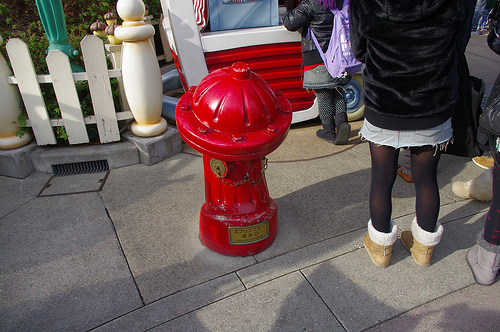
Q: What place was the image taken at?
A: It was taken at the sidewalk.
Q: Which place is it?
A: It is a sidewalk.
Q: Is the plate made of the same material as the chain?
A: Yes, both the plate and the chain are made of metal.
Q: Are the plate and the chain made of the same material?
A: Yes, both the plate and the chain are made of metal.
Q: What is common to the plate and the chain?
A: The material, both the plate and the chain are metallic.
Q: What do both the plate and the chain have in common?
A: The material, both the plate and the chain are metallic.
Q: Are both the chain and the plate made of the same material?
A: Yes, both the chain and the plate are made of metal.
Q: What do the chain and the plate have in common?
A: The material, both the chain and the plate are metallic.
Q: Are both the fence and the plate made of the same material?
A: No, the fence is made of wood and the plate is made of metal.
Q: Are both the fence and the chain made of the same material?
A: No, the fence is made of wood and the chain is made of metal.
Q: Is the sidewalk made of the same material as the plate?
A: No, the sidewalk is made of cement and the plate is made of metal.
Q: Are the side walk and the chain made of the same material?
A: No, the side walk is made of concrete and the chain is made of metal.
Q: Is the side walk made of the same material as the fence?
A: No, the side walk is made of concrete and the fence is made of wood.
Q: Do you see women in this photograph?
A: Yes, there is a woman.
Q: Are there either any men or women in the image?
A: Yes, there is a woman.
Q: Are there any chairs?
A: No, there are no chairs.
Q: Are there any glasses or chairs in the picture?
A: No, there are no chairs or glasses.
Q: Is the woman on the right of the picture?
A: Yes, the woman is on the right of the image.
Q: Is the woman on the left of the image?
A: No, the woman is on the right of the image.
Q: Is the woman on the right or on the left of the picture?
A: The woman is on the right of the image.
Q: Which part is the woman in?
A: The woman is on the right of the image.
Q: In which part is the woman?
A: The woman is on the right of the image.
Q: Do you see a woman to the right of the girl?
A: Yes, there is a woman to the right of the girl.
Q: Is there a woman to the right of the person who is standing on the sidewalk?
A: Yes, there is a woman to the right of the girl.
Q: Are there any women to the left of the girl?
A: No, the woman is to the right of the girl.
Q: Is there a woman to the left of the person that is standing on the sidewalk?
A: No, the woman is to the right of the girl.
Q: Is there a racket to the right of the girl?
A: No, there is a woman to the right of the girl.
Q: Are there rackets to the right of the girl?
A: No, there is a woman to the right of the girl.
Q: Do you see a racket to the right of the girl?
A: No, there is a woman to the right of the girl.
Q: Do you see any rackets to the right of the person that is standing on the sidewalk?
A: No, there is a woman to the right of the girl.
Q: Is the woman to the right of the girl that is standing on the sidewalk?
A: Yes, the woman is to the right of the girl.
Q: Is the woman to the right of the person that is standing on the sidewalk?
A: Yes, the woman is to the right of the girl.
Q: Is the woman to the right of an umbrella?
A: No, the woman is to the right of the girl.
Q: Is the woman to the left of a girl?
A: No, the woman is to the right of a girl.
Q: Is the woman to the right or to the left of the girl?
A: The woman is to the right of the girl.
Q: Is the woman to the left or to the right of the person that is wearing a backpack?
A: The woman is to the right of the girl.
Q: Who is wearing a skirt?
A: The woman is wearing a skirt.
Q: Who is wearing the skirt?
A: The woman is wearing a skirt.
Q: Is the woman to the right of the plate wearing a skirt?
A: Yes, the woman is wearing a skirt.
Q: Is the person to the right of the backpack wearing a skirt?
A: Yes, the woman is wearing a skirt.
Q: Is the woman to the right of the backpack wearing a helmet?
A: No, the woman is wearing a skirt.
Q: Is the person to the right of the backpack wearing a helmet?
A: No, the woman is wearing a skirt.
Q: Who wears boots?
A: The woman wears boots.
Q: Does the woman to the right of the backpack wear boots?
A: Yes, the woman wears boots.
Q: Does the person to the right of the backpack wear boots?
A: Yes, the woman wears boots.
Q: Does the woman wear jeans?
A: No, the woman wears boots.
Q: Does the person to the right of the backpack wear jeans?
A: No, the woman wears boots.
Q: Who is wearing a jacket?
A: The woman is wearing a jacket.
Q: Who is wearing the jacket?
A: The woman is wearing a jacket.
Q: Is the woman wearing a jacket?
A: Yes, the woman is wearing a jacket.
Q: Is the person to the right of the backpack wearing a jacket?
A: Yes, the woman is wearing a jacket.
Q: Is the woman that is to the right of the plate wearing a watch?
A: No, the woman is wearing a jacket.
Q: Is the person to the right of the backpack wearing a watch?
A: No, the woman is wearing a jacket.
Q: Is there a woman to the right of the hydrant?
A: Yes, there is a woman to the right of the hydrant.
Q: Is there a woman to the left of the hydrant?
A: No, the woman is to the right of the hydrant.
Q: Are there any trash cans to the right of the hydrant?
A: No, there is a woman to the right of the hydrant.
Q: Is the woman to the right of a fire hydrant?
A: Yes, the woman is to the right of a fire hydrant.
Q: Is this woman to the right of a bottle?
A: No, the woman is to the right of a fire hydrant.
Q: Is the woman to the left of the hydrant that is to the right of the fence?
A: No, the woman is to the right of the fire hydrant.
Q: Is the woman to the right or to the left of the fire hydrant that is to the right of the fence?
A: The woman is to the right of the fire hydrant.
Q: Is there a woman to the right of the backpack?
A: Yes, there is a woman to the right of the backpack.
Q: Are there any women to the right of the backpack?
A: Yes, there is a woman to the right of the backpack.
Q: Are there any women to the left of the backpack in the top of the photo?
A: No, the woman is to the right of the backpack.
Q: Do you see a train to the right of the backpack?
A: No, there is a woman to the right of the backpack.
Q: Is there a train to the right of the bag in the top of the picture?
A: No, there is a woman to the right of the backpack.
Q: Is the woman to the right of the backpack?
A: Yes, the woman is to the right of the backpack.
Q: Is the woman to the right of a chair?
A: No, the woman is to the right of the backpack.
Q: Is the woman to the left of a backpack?
A: No, the woman is to the right of a backpack.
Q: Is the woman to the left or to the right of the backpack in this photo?
A: The woman is to the right of the backpack.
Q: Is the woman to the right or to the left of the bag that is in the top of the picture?
A: The woman is to the right of the backpack.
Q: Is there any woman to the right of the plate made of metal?
A: Yes, there is a woman to the right of the plate.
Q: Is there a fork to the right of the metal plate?
A: No, there is a woman to the right of the plate.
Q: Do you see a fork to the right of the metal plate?
A: No, there is a woman to the right of the plate.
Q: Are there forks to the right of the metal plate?
A: No, there is a woman to the right of the plate.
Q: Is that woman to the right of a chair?
A: No, the woman is to the right of the plate.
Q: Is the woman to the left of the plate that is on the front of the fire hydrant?
A: No, the woman is to the right of the plate.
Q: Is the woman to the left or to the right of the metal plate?
A: The woman is to the right of the plate.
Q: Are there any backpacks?
A: Yes, there is a backpack.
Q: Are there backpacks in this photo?
A: Yes, there is a backpack.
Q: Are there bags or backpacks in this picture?
A: Yes, there is a backpack.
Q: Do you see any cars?
A: No, there are no cars.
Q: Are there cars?
A: No, there are no cars.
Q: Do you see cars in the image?
A: No, there are no cars.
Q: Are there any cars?
A: No, there are no cars.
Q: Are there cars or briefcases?
A: No, there are no cars or briefcases.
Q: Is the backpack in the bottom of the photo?
A: No, the backpack is in the top of the image.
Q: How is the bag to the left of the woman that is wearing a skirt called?
A: The bag is a backpack.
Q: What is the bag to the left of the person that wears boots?
A: The bag is a backpack.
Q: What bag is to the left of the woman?
A: The bag is a backpack.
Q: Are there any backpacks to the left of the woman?
A: Yes, there is a backpack to the left of the woman.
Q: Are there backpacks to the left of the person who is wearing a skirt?
A: Yes, there is a backpack to the left of the woman.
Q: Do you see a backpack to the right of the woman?
A: No, the backpack is to the left of the woman.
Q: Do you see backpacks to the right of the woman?
A: No, the backpack is to the left of the woman.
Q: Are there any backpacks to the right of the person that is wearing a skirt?
A: No, the backpack is to the left of the woman.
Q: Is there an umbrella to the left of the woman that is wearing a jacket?
A: No, there is a backpack to the left of the woman.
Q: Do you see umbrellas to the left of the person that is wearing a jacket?
A: No, there is a backpack to the left of the woman.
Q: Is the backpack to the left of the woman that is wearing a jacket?
A: Yes, the backpack is to the left of the woman.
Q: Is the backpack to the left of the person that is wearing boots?
A: Yes, the backpack is to the left of the woman.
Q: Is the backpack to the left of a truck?
A: No, the backpack is to the left of the woman.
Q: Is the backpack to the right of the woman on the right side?
A: No, the backpack is to the left of the woman.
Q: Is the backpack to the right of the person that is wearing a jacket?
A: No, the backpack is to the left of the woman.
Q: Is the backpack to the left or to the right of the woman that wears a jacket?
A: The backpack is to the left of the woman.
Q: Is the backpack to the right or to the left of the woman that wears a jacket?
A: The backpack is to the left of the woman.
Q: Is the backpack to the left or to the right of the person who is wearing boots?
A: The backpack is to the left of the woman.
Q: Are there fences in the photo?
A: Yes, there is a fence.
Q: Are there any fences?
A: Yes, there is a fence.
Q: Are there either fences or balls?
A: Yes, there is a fence.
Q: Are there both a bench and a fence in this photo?
A: No, there is a fence but no benches.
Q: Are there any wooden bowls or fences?
A: Yes, there is a wood fence.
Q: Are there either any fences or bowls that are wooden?
A: Yes, the fence is wooden.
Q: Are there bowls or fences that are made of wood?
A: Yes, the fence is made of wood.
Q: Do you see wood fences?
A: Yes, there is a wood fence.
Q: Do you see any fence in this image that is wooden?
A: Yes, there is a fence that is wooden.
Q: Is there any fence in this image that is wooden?
A: Yes, there is a fence that is wooden.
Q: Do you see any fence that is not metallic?
A: Yes, there is a wooden fence.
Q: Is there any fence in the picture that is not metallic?
A: Yes, there is a wooden fence.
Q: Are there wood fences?
A: Yes, there is a fence that is made of wood.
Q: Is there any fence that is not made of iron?
A: Yes, there is a fence that is made of wood.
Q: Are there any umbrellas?
A: No, there are no umbrellas.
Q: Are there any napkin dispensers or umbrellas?
A: No, there are no umbrellas or napkin dispensers.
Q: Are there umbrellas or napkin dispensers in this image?
A: No, there are no umbrellas or napkin dispensers.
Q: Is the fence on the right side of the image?
A: No, the fence is on the left of the image.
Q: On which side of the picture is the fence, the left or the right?
A: The fence is on the left of the image.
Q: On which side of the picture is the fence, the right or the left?
A: The fence is on the left of the image.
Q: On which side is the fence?
A: The fence is on the left of the image.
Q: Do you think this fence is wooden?
A: Yes, the fence is wooden.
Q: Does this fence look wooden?
A: Yes, the fence is wooden.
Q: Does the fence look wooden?
A: Yes, the fence is wooden.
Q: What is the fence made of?
A: The fence is made of wood.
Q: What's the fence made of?
A: The fence is made of wood.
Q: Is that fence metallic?
A: No, the fence is wooden.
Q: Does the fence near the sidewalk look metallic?
A: No, the fence is wooden.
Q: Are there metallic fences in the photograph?
A: No, there is a fence but it is wooden.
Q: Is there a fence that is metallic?
A: No, there is a fence but it is wooden.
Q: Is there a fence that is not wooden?
A: No, there is a fence but it is wooden.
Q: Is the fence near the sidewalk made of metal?
A: No, the fence is made of wood.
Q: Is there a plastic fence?
A: No, there is a fence but it is made of wood.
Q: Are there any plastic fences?
A: No, there is a fence but it is made of wood.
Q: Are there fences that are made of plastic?
A: No, there is a fence but it is made of wood.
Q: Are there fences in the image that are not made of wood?
A: No, there is a fence but it is made of wood.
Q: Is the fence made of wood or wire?
A: The fence is made of wood.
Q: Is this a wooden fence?
A: Yes, this is a wooden fence.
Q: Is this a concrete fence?
A: No, this is a wooden fence.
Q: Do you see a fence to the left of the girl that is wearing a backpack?
A: Yes, there is a fence to the left of the girl.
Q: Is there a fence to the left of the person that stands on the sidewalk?
A: Yes, there is a fence to the left of the girl.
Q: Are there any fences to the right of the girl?
A: No, the fence is to the left of the girl.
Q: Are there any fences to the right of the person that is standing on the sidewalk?
A: No, the fence is to the left of the girl.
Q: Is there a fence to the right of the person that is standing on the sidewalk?
A: No, the fence is to the left of the girl.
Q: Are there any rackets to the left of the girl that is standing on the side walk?
A: No, there is a fence to the left of the girl.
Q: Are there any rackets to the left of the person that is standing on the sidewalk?
A: No, there is a fence to the left of the girl.